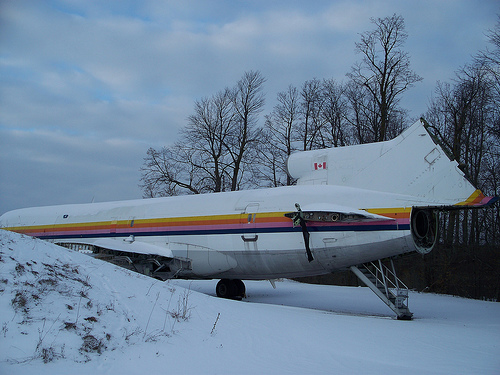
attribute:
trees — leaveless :
[444, 69, 499, 156]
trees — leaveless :
[194, 70, 264, 189]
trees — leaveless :
[353, 14, 413, 136]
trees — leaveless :
[261, 79, 350, 146]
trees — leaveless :
[199, 75, 353, 153]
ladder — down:
[349, 257, 414, 321]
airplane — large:
[4, 117, 496, 301]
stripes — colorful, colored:
[1, 205, 411, 239]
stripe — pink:
[233, 217, 273, 236]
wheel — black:
[212, 279, 249, 300]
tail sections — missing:
[280, 114, 489, 264]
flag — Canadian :
[307, 144, 336, 179]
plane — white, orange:
[21, 117, 491, 322]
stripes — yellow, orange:
[3, 189, 496, 241]